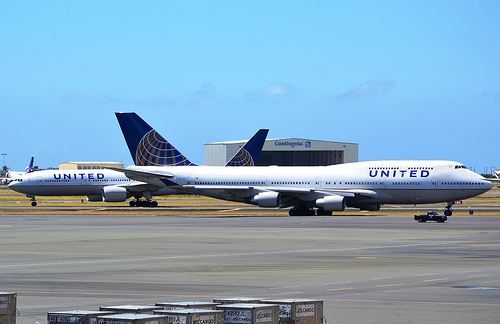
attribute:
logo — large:
[272, 139, 312, 151]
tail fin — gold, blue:
[107, 105, 197, 170]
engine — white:
[313, 192, 346, 210]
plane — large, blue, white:
[99, 110, 494, 219]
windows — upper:
[59, 86, 499, 298]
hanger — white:
[196, 120, 380, 179]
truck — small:
[408, 209, 455, 226]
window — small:
[438, 179, 449, 186]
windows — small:
[192, 180, 484, 186]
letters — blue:
[369, 161, 434, 181]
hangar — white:
[206, 136, 358, 165]